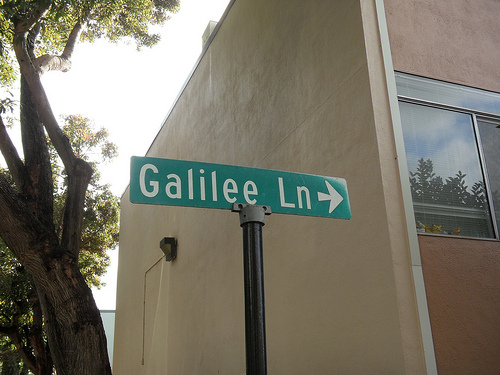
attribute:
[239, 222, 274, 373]
pole — metal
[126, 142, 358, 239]
sign — white, green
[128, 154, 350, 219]
sign — green, white, green street , White letter G 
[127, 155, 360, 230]
letters — white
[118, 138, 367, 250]
sign — green, white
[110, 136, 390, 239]
sign — Green street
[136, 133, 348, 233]
sign — black, metal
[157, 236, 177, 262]
lamp — black 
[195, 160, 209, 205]
letter — I 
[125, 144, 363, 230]
sign —  green street, green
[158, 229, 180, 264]
lamp — side 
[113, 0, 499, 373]
building — apartment , orange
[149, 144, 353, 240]
street sign — green street 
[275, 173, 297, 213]
letter l — white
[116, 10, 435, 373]
wall — beige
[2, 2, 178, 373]
tree — tall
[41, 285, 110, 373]
trunk — brown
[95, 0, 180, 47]
leaves — green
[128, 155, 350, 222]
street sign — green, white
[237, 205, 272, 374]
pole — black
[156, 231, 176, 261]
holder — outdoor electrical 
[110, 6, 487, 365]
apartment — side 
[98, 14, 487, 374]
building — side 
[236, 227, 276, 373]
pole — black metal 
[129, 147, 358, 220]
sign — green street , White letter A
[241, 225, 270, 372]
pole — metal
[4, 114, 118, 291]
leaves — green